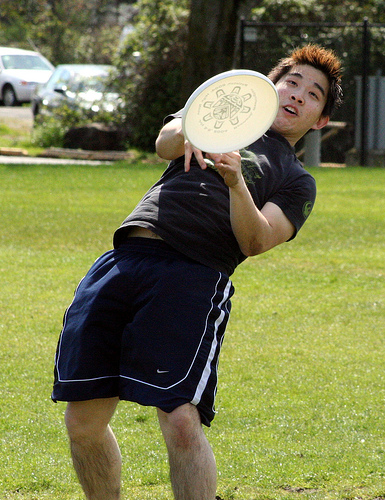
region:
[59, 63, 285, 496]
guy catching frisbee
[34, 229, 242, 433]
navy blue men's nike shorts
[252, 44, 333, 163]
guy of asian race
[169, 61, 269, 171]
round white frisbee disc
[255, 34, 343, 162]
guy with black hair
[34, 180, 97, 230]
green grass patch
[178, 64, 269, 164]
white frisbee with black design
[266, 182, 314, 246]
black tshirt with green design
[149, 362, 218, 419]
white nike symbol on shorts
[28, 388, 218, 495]
legs of person with hair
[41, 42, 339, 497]
man with frisbee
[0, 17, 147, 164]
two cars are parked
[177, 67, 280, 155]
the frisbee is white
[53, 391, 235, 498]
the man has hair on his legs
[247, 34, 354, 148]
the man's hair is auburn colored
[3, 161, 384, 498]
the grass is green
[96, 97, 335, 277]
the man is wearing a blue shirt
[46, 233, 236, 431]
the man is wearing blue shorts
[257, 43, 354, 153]
the man has dark eyebrows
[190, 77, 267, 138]
the frisbee has black writing on it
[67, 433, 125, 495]
Man's hairy right leg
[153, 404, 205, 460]
Man's left knee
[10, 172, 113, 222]
Green grass behind the man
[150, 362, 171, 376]
'Nike' emblem on the man's shorts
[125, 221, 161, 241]
Man's stomach underneath his shirt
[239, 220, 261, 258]
Man's left elbow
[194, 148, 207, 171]
Man's right ring finger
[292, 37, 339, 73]
Spiky hair on the top of the man's head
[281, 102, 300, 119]
Man's open mouth and teeth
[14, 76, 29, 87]
Tail light on the car in the background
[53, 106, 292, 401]
a boy with black attire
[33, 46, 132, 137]
a black car on the parking spot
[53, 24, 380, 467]
a boy is bent while playing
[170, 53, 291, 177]
a boy holding plate on his hand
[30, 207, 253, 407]
a boy has a short on him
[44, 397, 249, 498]
a boy is stepping on the grass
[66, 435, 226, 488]
a boy has black hair on his legs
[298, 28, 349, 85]
a boy with brown hair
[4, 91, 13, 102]
a car with silver cap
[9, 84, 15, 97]
a car with black tires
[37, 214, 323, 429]
a man with blue short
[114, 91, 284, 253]
a man with blue shirt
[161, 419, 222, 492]
a man with black hair on his leg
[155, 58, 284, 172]
a man holding a plate while playing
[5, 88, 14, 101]
a car with silver wheel cap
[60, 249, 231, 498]
a man standing on the ground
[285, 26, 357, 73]
a man with brown hair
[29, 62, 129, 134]
a car is packed on the parking lot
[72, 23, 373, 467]
a boy is bent while playing.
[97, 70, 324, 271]
a man with a blue shirt